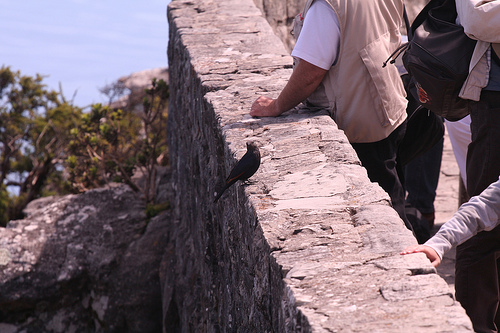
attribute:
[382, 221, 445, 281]
wall — rock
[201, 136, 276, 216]
bird — standing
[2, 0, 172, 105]
water — calm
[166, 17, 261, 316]
wall — rock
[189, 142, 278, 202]
bird — small 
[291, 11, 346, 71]
shirt — white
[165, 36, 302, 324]
wall — rock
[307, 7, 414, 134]
vest — light brown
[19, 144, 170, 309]
boulder — large, grey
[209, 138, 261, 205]
bird — small 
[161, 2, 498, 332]
wall — rock, brick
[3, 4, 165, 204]
sky — blue 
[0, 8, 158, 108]
water — large, body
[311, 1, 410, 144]
vest — tan